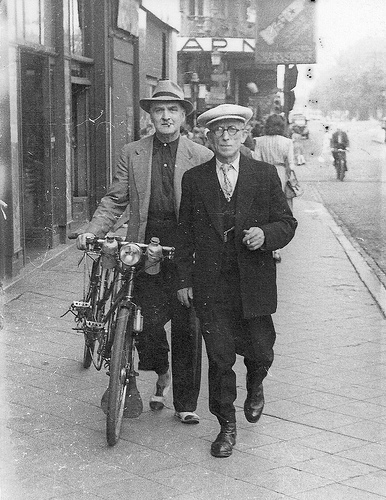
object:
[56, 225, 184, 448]
bike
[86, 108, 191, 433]
man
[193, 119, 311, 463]
man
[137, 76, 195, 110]
hat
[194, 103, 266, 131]
hat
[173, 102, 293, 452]
man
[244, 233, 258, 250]
cigarette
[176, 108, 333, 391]
man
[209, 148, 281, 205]
tie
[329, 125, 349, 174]
man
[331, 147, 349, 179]
bicycle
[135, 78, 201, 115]
fedora hat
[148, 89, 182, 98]
black stripe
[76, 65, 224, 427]
man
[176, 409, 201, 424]
shoes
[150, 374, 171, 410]
shoes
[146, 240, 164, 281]
metal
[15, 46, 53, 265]
door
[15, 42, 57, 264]
trim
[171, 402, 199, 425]
shoe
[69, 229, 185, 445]
bicycle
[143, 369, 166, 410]
shoes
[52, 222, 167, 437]
bicucle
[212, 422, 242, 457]
shoe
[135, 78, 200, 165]
man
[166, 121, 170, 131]
cigar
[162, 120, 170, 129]
mouth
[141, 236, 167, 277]
metal bottle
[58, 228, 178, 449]
bicycle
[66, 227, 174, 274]
handle bars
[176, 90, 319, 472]
person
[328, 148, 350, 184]
motorcycle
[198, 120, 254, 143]
glasses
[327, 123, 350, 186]
person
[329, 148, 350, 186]
bicycle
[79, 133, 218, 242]
jacket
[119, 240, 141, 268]
headlight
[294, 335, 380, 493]
pavement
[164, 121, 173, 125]
cigarette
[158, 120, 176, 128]
mouth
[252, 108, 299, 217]
person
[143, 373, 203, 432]
shoes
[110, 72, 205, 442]
man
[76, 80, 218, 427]
man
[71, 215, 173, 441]
bike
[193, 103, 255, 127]
hat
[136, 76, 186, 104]
hat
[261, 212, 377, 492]
sidewalk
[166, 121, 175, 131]
cigar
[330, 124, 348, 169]
person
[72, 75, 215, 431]
person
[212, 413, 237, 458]
boot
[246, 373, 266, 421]
boot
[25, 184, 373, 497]
pavement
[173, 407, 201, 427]
shoe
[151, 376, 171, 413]
shoe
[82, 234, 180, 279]
handlebars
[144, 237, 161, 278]
bottle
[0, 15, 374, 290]
distance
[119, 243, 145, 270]
headlight